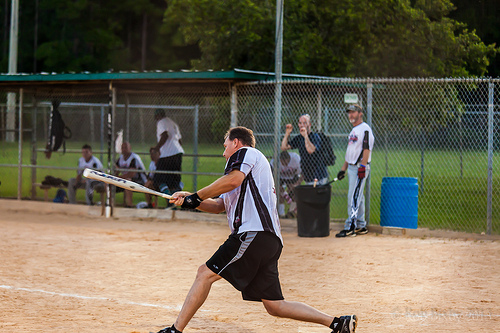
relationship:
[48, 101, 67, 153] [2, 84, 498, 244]
bag hanging on fence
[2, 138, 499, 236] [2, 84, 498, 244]
grass behind fence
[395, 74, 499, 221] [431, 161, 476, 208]
fence on grass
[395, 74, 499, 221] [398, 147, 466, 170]
fence on grass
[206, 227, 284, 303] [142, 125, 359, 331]
shorts on man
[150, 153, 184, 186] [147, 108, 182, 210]
shorts on man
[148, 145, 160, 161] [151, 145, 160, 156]
glove on hand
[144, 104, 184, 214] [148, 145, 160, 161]
man wears glove